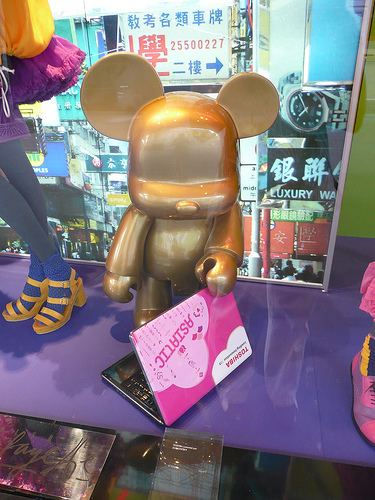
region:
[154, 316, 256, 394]
the computer is pink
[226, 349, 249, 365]
the brand is Toshiba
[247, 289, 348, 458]
the platform is purple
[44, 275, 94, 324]
the shoes are yellow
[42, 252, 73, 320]
the socks are blue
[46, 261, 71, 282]
pattern on the socks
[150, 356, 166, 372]
a letter written in pink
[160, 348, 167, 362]
a letter written in pink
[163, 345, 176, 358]
a letter written in pink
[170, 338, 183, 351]
a letter written in pink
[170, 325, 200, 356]
a letter written in pink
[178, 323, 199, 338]
a letter written in pink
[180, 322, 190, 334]
a letter written in pink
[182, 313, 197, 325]
a letter written in pink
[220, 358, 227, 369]
a letter written in pink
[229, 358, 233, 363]
a letter written in pink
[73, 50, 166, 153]
Ear of the statue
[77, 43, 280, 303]
A statue of a mouse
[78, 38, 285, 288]
Large statue of a mouse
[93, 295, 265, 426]
The laptop is open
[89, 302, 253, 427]
The laptop is pink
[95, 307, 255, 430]
The laptop is pink on the outside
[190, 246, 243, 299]
Hand of the statue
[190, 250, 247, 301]
Hand of the gold statue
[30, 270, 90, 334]
The shoe has a heel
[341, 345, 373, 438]
The shoe is pink and purple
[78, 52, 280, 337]
gold bear statue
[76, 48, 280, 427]
gold bear statue opening a laptop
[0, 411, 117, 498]
shiny plate with cursive writing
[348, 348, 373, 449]
pink and purple shoe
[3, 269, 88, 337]
brown strappy heel sandals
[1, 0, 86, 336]
manikin wearing black tights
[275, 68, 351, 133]
silver watch with black face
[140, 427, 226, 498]
empty plastic zip bag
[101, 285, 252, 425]
a pink and black laptop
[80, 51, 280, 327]
a large bronze statue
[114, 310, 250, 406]
a laptop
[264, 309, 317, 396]
the reflection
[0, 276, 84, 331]
two shoes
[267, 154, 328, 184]
writing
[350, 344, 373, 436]
a shoe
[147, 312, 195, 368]
writing on the laptop is pink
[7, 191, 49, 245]
leggings are blue